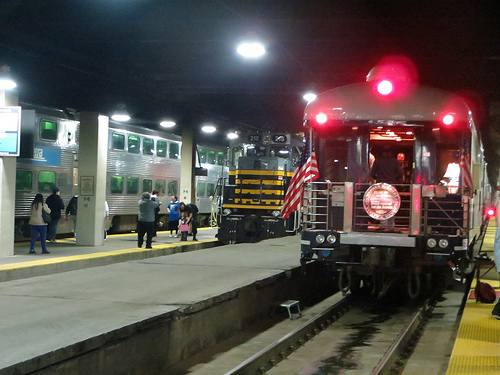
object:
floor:
[0, 211, 500, 375]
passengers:
[45, 187, 66, 244]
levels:
[150, 247, 225, 276]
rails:
[223, 283, 434, 375]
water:
[311, 305, 401, 373]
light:
[225, 131, 239, 141]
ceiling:
[0, 0, 329, 163]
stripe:
[223, 170, 295, 209]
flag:
[277, 151, 320, 220]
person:
[370, 147, 405, 232]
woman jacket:
[29, 202, 52, 226]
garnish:
[91, 240, 138, 270]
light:
[113, 112, 133, 123]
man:
[136, 192, 161, 249]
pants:
[137, 222, 154, 248]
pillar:
[73, 115, 111, 246]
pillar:
[0, 66, 24, 256]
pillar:
[178, 128, 198, 236]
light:
[235, 40, 265, 60]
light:
[0, 78, 16, 90]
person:
[151, 190, 164, 240]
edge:
[0, 259, 319, 374]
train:
[290, 58, 489, 304]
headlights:
[442, 115, 456, 126]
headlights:
[378, 81, 394, 95]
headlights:
[316, 112, 330, 124]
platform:
[0, 225, 309, 370]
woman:
[27, 193, 52, 255]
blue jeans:
[30, 225, 47, 251]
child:
[177, 212, 190, 241]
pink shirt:
[180, 224, 189, 232]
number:
[250, 135, 260, 141]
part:
[195, 282, 263, 308]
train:
[214, 130, 311, 249]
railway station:
[0, 0, 499, 375]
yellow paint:
[446, 215, 500, 375]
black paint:
[226, 170, 294, 210]